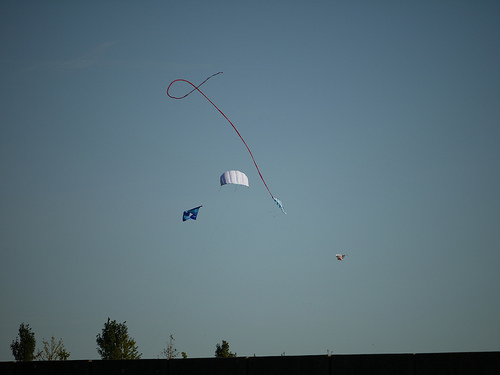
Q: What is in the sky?
A: Clouds.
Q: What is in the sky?
A: Clouds.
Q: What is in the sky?
A: Kite.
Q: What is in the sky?
A: Kites.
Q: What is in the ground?
A: Trees.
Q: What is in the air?
A: Red tail.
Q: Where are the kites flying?
A: Air.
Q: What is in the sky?
A: Clouds.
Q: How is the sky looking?
A: Clear.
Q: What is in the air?
A: Lights.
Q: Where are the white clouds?
A: In the light blue sky.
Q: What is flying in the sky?
A: Four kites.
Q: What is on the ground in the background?
A: A cluster of leafy trees.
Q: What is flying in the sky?
A: A group of kites.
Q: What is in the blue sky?
A: White clouds.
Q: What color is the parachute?
A: White.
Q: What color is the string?
A: Red.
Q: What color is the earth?
A: Brown.